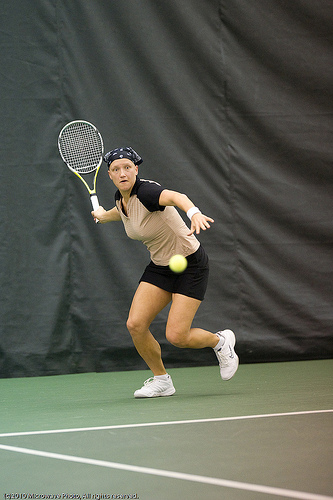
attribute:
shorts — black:
[139, 245, 208, 299]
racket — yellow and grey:
[58, 119, 104, 221]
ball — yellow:
[169, 252, 187, 272]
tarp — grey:
[0, 0, 333, 377]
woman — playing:
[20, 71, 267, 430]